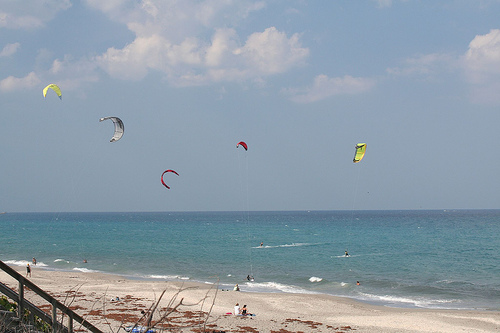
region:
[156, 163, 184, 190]
a kite in the sky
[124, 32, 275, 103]
the cloud is white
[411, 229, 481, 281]
the water is blue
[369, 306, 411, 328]
sand on the beach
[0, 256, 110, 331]
wooden railing of stairs leading to beach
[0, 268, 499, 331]
wide expanse of sand along an ocean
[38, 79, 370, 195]
five kites being flown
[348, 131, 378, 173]
yellow kite flying in the air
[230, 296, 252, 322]
two people sitting on a beach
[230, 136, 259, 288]
person on beach flying red kite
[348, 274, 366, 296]
person swimming in the ocean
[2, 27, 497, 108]
white puffy clouds in a blue sky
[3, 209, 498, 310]
beautiful blue ocean waters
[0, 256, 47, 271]
white waves crashing on the beach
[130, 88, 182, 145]
white clouds in blue sky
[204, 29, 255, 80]
white clouds in blue sky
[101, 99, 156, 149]
white clouds in blue sky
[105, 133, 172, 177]
white clouds in blue sky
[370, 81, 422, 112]
white clouds in blue sky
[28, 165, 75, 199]
white clouds in blue sky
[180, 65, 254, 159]
kites and white clouds in blue sky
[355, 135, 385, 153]
kites and white clouds in blue sky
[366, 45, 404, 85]
kites and white clouds in blue sky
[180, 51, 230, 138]
kites and white clouds in blue sky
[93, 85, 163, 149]
kites and white clouds in blue sky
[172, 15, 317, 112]
clouds in the sky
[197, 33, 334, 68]
white clouds above water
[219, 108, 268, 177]
object in the air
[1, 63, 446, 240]
many objects in air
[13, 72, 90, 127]
yellow object in the air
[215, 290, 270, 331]
people on the beach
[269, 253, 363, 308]
wave in the water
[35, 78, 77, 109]
yellow kite seen in the far left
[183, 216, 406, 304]
People are kite surfing on the water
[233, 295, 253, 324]
Couple sitting on the beach as they watch the surfers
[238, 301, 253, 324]
a person is standing up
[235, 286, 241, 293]
a person is sitting down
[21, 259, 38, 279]
a person is standing up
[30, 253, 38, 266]
a person is standing up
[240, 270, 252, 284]
a person is standing up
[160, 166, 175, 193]
a kite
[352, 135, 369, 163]
a kite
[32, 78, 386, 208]
C-kites in the sky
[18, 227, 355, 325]
people in the beach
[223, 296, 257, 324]
people sits on the sand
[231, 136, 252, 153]
the C kite is red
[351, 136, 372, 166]
the C kite is yellow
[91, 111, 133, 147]
the C kite is gray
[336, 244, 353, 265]
a person in the water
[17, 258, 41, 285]
a person walking in the beach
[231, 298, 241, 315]
person wears white top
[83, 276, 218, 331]
a branch on wood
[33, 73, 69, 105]
a C-kite in the sky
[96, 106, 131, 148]
a C-kite in the sky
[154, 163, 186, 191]
a C-kite in the sky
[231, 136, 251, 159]
a C-kite in the sky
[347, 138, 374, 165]
a C-kite is colro yellow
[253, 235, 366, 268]
people in the water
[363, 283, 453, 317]
waves in the sea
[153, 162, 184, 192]
the kite is red